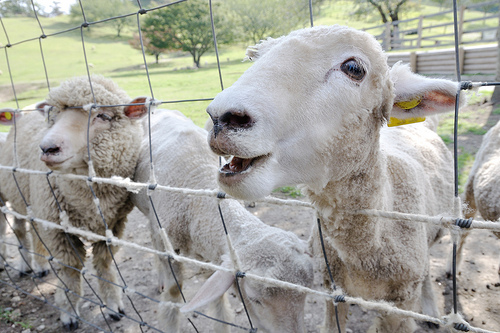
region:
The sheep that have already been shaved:
[135, 23, 499, 329]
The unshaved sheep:
[0, 77, 152, 320]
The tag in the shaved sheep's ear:
[386, 93, 431, 135]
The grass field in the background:
[4, 0, 484, 202]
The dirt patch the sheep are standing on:
[3, 183, 499, 331]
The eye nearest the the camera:
[338, 54, 371, 96]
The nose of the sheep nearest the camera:
[205, 96, 260, 137]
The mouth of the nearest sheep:
[216, 145, 268, 182]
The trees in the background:
[67, 1, 444, 66]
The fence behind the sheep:
[308, 0, 499, 93]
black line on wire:
[203, 188, 248, 213]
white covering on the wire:
[238, 276, 345, 310]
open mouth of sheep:
[203, 145, 298, 206]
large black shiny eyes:
[337, 53, 380, 99]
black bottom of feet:
[50, 310, 94, 327]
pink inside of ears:
[399, 70, 454, 135]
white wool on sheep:
[263, 90, 333, 141]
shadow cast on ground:
[166, 57, 246, 100]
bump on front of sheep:
[280, 30, 318, 56]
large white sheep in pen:
[178, 15, 438, 251]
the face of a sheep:
[179, 18, 483, 233]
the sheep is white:
[21, 70, 173, 230]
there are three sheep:
[19, 48, 449, 326]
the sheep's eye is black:
[321, 39, 394, 106]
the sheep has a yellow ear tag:
[360, 50, 462, 155]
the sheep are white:
[30, 64, 361, 331]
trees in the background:
[73, 7, 232, 158]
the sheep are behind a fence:
[26, 16, 460, 288]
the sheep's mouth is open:
[185, 61, 343, 224]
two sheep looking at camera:
[21, 37, 466, 262]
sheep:
[21, 26, 491, 325]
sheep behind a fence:
[8, 35, 495, 300]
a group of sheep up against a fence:
[18, 60, 498, 332]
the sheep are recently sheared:
[147, 36, 499, 314]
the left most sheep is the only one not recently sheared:
[7, 74, 152, 331]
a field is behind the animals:
[30, 11, 313, 110]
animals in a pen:
[0, 48, 497, 329]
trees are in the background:
[68, 0, 436, 57]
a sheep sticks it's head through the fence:
[214, 21, 469, 239]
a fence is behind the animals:
[268, 16, 498, 78]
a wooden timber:
[413, 50, 461, 60]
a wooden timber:
[413, 61, 454, 66]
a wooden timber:
[463, 57, 499, 65]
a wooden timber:
[467, 46, 498, 53]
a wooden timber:
[459, 70, 497, 79]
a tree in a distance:
[144, 1, 237, 68]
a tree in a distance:
[60, 0, 132, 32]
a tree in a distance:
[111, 5, 149, 37]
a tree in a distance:
[225, 4, 283, 39]